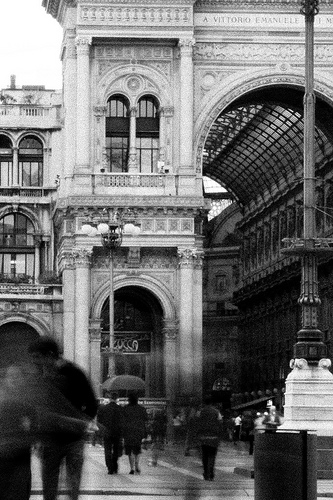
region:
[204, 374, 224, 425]
Black umbrella getting wet by rain.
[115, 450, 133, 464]
Black umbrella getting wet by rain.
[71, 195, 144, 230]
vBlack umbrella getting wet by rain.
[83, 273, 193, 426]
archway on the building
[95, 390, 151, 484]
a man walking next to a woman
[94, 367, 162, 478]
two people under an umbrella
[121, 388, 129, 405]
thin rod on the umbrella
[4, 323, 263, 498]
people on the walkway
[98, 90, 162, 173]
two windows on the side of the building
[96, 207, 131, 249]
light on top of a pole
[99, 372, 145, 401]
umbrella is open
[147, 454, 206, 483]
line on the ground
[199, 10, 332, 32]
writing on the top of the building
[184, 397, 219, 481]
the person is walking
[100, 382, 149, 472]
the people are walking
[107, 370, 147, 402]
umbrella over the people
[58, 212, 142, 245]
lights on the structure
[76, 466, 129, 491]
the ground is wet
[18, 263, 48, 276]
window of the building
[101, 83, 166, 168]
the windows are arched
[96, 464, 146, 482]
feet of the people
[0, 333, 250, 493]
people walking on a wet street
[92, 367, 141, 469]
man and woman under dark umbrella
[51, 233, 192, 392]
columns of both sides of arched entryway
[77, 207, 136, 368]
lamppost with white globes in a circle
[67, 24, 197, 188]
stone railing between two columns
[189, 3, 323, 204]
curved support beams supporting roof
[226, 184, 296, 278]
border of ornate medallions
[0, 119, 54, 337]
arches on different levels in a vertical line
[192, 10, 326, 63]
borders on building with writing and pattern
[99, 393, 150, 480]
a man and a woman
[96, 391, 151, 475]
two people walking together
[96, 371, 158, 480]
two people standing under an umbrella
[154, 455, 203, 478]
line on the ground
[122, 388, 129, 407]
thin umbrella rod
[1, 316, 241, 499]
people on the walkway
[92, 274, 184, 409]
arch on the building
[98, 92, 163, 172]
two windows on the building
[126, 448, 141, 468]
skin on the legs is exposed